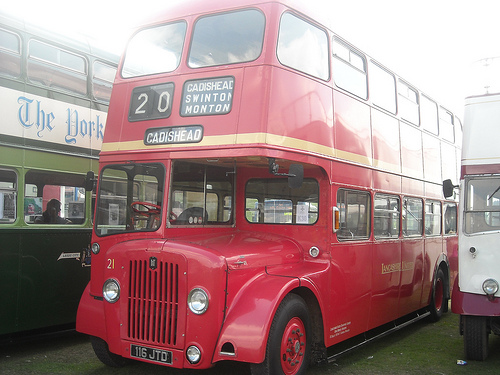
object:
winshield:
[243, 177, 320, 224]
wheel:
[129, 200, 179, 222]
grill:
[120, 249, 186, 348]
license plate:
[130, 343, 174, 366]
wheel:
[250, 290, 312, 374]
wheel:
[428, 268, 447, 320]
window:
[245, 175, 320, 225]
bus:
[77, 0, 464, 374]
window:
[442, 201, 458, 236]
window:
[367, 59, 398, 116]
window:
[166, 160, 237, 225]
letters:
[148, 348, 156, 359]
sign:
[142, 123, 205, 145]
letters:
[193, 128, 201, 141]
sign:
[128, 81, 175, 122]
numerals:
[133, 92, 150, 115]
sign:
[179, 74, 235, 118]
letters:
[183, 105, 195, 114]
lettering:
[380, 261, 415, 274]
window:
[93, 163, 166, 237]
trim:
[99, 142, 463, 188]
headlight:
[102, 277, 123, 304]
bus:
[442, 92, 499, 361]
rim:
[279, 316, 305, 374]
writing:
[380, 260, 413, 274]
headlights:
[185, 286, 209, 314]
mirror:
[441, 178, 453, 197]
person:
[42, 198, 72, 225]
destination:
[183, 103, 231, 113]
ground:
[0, 299, 499, 373]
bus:
[0, 12, 227, 345]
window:
[187, 8, 266, 69]